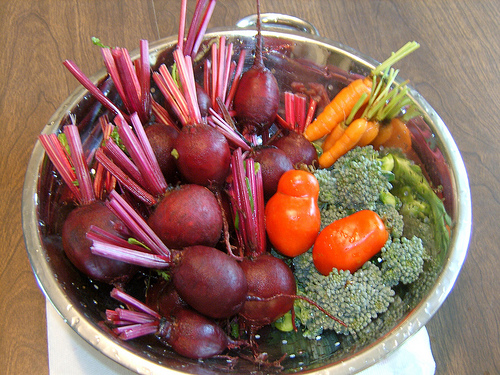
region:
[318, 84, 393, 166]
orange carrots in bowl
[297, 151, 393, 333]
broccoli in metal bowl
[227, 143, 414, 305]
orange peppers in bowl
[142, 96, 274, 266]
purple radishes in bowl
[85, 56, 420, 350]
bowl is large and metal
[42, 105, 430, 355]
bowl on white platform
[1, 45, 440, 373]
bowl on brown table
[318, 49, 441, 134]
carrots have green stems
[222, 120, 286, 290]
radishes have purple stems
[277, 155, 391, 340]
green broccoli is uncooked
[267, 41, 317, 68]
Food reflection in stainless steel bowl.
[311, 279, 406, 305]
Brocolli floret head buds and flowers.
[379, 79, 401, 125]
Green baby carrot stems.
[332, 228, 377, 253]
Clear water drops on a tomato.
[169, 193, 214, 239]
The skin of a deep red beet.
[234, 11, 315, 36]
Stainless steel bowl handle.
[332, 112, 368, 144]
Crisp baby orange carrots.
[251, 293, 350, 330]
The main root of a beet.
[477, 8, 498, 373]
Brown colored wood grain tabletop.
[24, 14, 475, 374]
A bowl of fresh vegetables.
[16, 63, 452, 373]
the bowl is full of vegetables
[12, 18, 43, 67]
the table is made of wood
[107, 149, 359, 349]
beets are in the bowl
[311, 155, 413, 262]
broccoli is in teh bowl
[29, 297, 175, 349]
the cutting board is white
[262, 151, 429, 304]
tomatoes are in the bowl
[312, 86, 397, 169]
carrots are in the bowl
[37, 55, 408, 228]
the bowl is silver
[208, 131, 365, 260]
the beets have stems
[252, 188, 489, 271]
two tomatoes are in the bowl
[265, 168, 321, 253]
cherry tomato disfigured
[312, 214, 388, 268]
cherry tomato with normal shape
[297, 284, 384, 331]
small, raw broccoli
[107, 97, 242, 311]
cluster go whole, raw radishes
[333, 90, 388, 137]
baby carrots with stems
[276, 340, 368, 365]
iron bowl for holding ingredients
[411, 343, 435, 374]
white towel to dry of water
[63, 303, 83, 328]
water droplets on bowl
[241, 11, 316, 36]
handle to hold bowl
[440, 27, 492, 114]
wooden table to hold bowl on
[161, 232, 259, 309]
red vegetable in pot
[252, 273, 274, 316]
red vegetable in pot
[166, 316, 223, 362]
red vegetable in pot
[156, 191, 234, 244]
red vegetable in pot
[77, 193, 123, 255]
red vegetable in pot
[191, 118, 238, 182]
red vegetable in pot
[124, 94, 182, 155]
red vegetable in pot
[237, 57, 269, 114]
red vegetable in pot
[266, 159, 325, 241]
orange vegetable in pot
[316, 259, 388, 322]
broccoli in silver pot